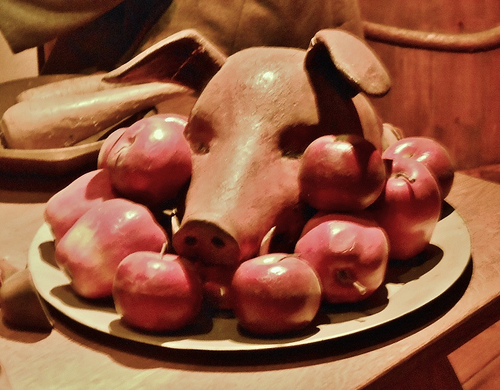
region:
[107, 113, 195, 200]
a ripe red apple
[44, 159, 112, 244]
a ripe red apple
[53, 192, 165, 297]
a ripe red apple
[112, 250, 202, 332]
a ripe red apple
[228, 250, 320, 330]
a ripe red apple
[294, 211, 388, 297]
a ripe red apple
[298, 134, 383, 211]
a ripe red apple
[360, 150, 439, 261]
a ripe red apple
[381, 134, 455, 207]
a ripe red apple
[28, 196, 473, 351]
a white dinner plate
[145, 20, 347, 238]
brown head of pig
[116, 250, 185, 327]
red apple on plate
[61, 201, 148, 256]
red apple on plate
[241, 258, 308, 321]
red apple on plate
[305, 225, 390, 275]
red apple on plate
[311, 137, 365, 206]
red apple on plate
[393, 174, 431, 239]
red apple on plate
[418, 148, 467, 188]
red apple on plate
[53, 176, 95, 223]
red apple on plate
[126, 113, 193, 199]
red apple on plate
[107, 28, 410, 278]
Fake pigs head on tray.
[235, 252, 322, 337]
Red apple on tray.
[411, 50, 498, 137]
Wood paneling on wall.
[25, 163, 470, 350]
White serving tray on table.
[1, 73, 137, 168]
Brown wooden bowl on table.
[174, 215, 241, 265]
Nostrils in animals snout.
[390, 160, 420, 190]
Brown stem on apple.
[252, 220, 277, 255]
White boar's tooth on animal.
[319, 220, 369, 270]
Dent in red apple.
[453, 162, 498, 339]
Wooden table top.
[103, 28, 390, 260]
A pigs disembodied head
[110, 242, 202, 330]
A red shiny apple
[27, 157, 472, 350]
A large round white platter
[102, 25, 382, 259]
Wood carving of a pigs head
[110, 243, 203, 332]
Wood carving of a red apple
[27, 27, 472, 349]
A white plate with wood carvings on it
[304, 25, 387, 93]
A pig's left ear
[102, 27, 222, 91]
A pig's right ear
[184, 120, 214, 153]
A pig's right eye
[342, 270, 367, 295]
Stem of a red apple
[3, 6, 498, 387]
a work of art with clay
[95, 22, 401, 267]
head of pig made with clay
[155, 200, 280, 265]
two fangs on mouth of pig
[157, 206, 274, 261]
fangs are color white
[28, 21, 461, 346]
apples of clay are around a pig's head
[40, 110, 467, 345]
apples are color red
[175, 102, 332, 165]
two holes in the place of eyes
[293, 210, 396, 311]
a red apple with a stem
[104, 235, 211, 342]
a red apple with a stem on border of dish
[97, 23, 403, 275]
head of pig is brown